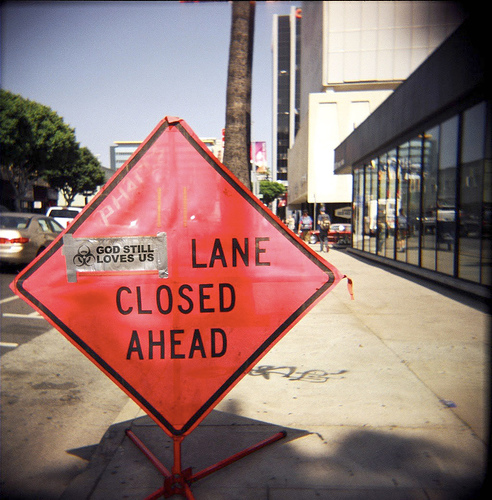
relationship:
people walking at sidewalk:
[269, 195, 338, 244] [321, 249, 466, 495]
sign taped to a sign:
[41, 135, 217, 306] [4, 111, 342, 443]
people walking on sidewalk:
[292, 202, 334, 249] [0, 235, 492, 498]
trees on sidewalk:
[0, 93, 103, 213] [9, 195, 84, 216]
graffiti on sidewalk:
[247, 353, 349, 383] [0, 235, 492, 498]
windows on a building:
[348, 115, 491, 288] [329, 7, 490, 320]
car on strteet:
[0, 205, 70, 279] [0, 269, 54, 358]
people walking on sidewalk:
[316, 202, 330, 254] [249, 206, 451, 489]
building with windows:
[329, 7, 490, 320] [350, 163, 454, 250]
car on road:
[0, 205, 70, 279] [0, 254, 56, 366]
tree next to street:
[223, 3, 256, 194] [3, 257, 52, 350]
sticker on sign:
[62, 231, 166, 281] [4, 111, 342, 443]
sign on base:
[4, 111, 342, 443] [123, 427, 286, 497]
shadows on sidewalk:
[64, 401, 486, 497] [387, 286, 434, 353]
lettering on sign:
[114, 223, 270, 364] [4, 111, 342, 443]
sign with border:
[4, 111, 342, 443] [230, 358, 247, 378]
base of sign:
[123, 427, 286, 497] [4, 111, 342, 443]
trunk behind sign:
[226, 3, 261, 193] [4, 111, 342, 443]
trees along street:
[0, 93, 103, 213] [0, 252, 56, 353]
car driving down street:
[4, 205, 99, 285] [3, 257, 52, 350]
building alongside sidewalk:
[329, 7, 490, 320] [281, 238, 467, 498]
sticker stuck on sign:
[62, 231, 166, 281] [4, 111, 342, 443]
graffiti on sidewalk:
[96, 162, 148, 223] [0, 235, 492, 498]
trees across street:
[5, 93, 103, 185] [0, 260, 50, 350]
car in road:
[0, 205, 70, 279] [1, 262, 57, 356]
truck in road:
[23, 200, 78, 233] [0, 269, 35, 346]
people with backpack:
[316, 202, 330, 254] [318, 211, 333, 231]